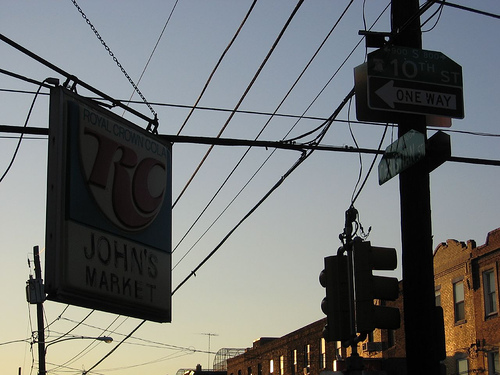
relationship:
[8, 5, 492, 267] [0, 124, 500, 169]
blue sky over utility lines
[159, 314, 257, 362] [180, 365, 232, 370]
antenna on top of building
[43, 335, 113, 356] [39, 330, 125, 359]
light on pole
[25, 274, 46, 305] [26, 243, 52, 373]
equipment on pole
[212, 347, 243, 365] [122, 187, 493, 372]
greenhouse on top of building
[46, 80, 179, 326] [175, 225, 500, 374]
sign before building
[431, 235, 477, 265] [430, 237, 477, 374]
ornamental top on building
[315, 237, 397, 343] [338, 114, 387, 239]
traffic lights on wire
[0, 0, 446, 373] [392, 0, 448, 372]
utility lines on pole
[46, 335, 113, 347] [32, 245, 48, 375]
light on pole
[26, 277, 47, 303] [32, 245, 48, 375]
equipment on pole